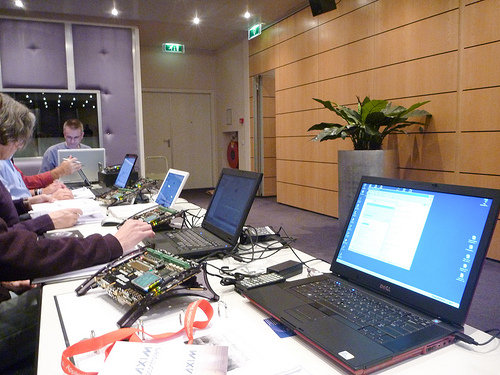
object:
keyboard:
[161, 227, 220, 253]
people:
[0, 93, 153, 278]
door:
[255, 74, 275, 196]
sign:
[162, 42, 186, 54]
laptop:
[143, 167, 264, 256]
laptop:
[107, 168, 189, 219]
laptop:
[89, 153, 138, 197]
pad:
[283, 300, 330, 325]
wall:
[247, 2, 498, 264]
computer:
[56, 147, 108, 183]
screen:
[114, 157, 136, 187]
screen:
[154, 172, 185, 210]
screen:
[203, 174, 256, 237]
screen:
[335, 181, 493, 308]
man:
[38, 118, 98, 177]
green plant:
[308, 95, 433, 150]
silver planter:
[335, 182, 495, 310]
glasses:
[64, 133, 83, 140]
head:
[63, 120, 85, 148]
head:
[0, 92, 35, 159]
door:
[141, 91, 214, 190]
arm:
[1, 227, 112, 282]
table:
[37, 181, 499, 373]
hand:
[45, 208, 83, 229]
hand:
[28, 194, 56, 204]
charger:
[267, 260, 304, 280]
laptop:
[235, 176, 500, 375]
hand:
[115, 219, 156, 253]